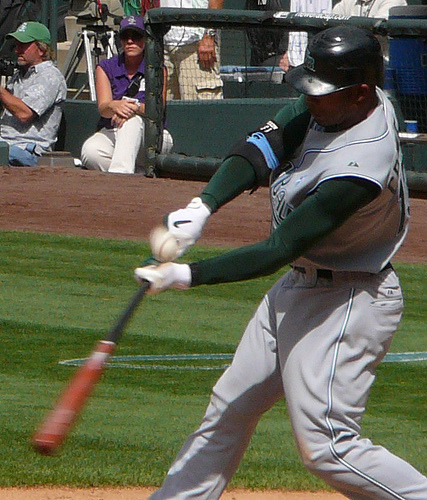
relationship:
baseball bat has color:
[30, 253, 162, 455] [33, 340, 121, 458]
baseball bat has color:
[30, 253, 162, 455] [108, 257, 166, 345]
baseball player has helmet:
[135, 21, 427, 499] [282, 24, 384, 95]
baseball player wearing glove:
[135, 21, 427, 499] [167, 195, 211, 260]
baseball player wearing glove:
[135, 21, 427, 499] [137, 258, 193, 290]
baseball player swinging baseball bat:
[135, 21, 427, 499] [30, 253, 162, 455]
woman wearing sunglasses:
[77, 15, 180, 177] [121, 30, 144, 43]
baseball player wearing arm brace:
[135, 21, 427, 499] [224, 108, 289, 208]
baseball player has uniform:
[135, 21, 427, 499] [150, 86, 424, 497]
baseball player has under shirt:
[135, 21, 427, 499] [187, 81, 379, 286]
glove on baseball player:
[167, 195, 211, 260] [135, 21, 427, 499]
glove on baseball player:
[137, 258, 193, 290] [135, 21, 427, 499]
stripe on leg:
[327, 284, 407, 497] [276, 259, 427, 496]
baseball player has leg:
[135, 21, 427, 499] [276, 259, 427, 496]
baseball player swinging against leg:
[135, 21, 427, 499] [150, 269, 298, 499]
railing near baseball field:
[140, 1, 426, 185] [2, 156, 427, 497]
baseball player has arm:
[135, 21, 427, 499] [136, 162, 381, 295]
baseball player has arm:
[135, 21, 427, 499] [170, 83, 317, 256]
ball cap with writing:
[5, 21, 53, 43] [17, 23, 33, 33]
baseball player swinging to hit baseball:
[135, 21, 427, 499] [146, 227, 182, 265]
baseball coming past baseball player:
[146, 227, 182, 265] [135, 21, 427, 499]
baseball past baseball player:
[146, 227, 182, 265] [135, 21, 427, 499]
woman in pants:
[77, 15, 180, 177] [78, 115, 177, 178]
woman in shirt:
[77, 15, 180, 177] [93, 51, 164, 131]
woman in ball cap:
[77, 15, 180, 177] [118, 16, 150, 41]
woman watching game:
[77, 15, 180, 177] [7, 15, 423, 494]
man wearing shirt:
[0, 19, 68, 169] [2, 56, 70, 156]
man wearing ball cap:
[0, 19, 68, 169] [5, 21, 53, 43]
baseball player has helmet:
[141, 21, 427, 496] [282, 24, 384, 95]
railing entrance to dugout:
[140, 1, 426, 185] [173, 69, 426, 157]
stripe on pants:
[327, 284, 407, 497] [148, 253, 422, 495]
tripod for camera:
[61, 25, 128, 100] [76, 0, 127, 38]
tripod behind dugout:
[61, 25, 128, 100] [173, 69, 426, 157]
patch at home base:
[1, 166, 426, 265] [65, 322, 426, 384]